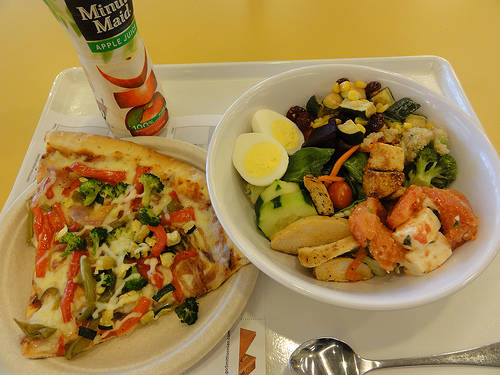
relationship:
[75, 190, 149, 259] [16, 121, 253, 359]
toppings on pizza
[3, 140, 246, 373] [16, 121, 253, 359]
plate with food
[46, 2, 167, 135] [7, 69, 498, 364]
bottle on tray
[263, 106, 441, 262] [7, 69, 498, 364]
food on tray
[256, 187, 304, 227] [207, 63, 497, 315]
vegetables on plate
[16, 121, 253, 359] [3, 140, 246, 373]
pizza on plate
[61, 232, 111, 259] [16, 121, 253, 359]
broccoli on pizza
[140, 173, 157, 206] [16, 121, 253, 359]
broccoli on pizza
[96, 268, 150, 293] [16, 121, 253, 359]
broccoli on top of pizza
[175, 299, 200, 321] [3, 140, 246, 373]
broccoli on plate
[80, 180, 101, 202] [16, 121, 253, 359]
broccoli on pizza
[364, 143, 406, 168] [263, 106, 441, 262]
crouton on salad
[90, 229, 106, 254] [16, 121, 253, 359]
broccoli on pizza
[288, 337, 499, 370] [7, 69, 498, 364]
spoon on tray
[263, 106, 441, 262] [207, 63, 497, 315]
food in bowl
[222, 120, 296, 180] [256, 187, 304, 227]
eggs next to cucumber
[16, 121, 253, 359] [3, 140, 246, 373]
pizza on top of plate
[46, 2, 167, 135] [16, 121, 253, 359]
bottle behind pizza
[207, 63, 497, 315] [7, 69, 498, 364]
bowl on tray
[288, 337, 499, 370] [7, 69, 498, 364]
silver spoon on tray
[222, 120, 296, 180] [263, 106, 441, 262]
eggs in salad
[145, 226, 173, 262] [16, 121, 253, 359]
peppers on top of pizza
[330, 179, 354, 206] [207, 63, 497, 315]
tomato in bowl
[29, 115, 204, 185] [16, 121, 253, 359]
paper under pizza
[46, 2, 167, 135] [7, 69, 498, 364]
apple juice on tray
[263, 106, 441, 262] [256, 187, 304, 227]
salad with vegetables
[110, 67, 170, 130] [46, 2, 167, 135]
apples on bottle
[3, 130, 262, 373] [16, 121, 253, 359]
plate full of food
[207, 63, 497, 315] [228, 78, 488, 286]
plate full of food